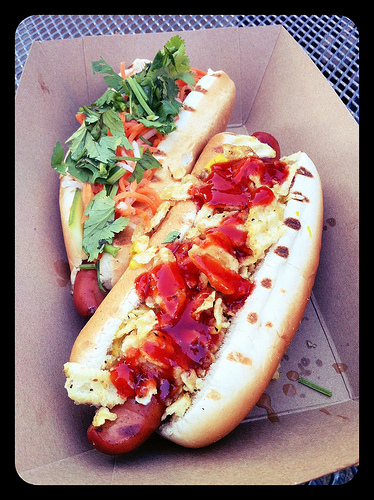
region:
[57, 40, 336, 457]
gourmet hotdogs in a tray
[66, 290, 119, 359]
white bun of a hotdog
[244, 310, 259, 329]
brown spot on bun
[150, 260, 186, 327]
sauce on a hotdog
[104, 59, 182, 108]
green cilantro on a hotdog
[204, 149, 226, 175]
mustard on a hotdog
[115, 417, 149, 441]
grill mark on a hotdog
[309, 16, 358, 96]
metal table under hotdogs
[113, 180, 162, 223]
tomatoes on a hotdog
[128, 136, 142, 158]
onion on a hotdog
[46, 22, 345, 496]
Two hot dogs in a box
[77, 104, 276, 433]
Hot dogs on buns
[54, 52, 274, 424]
The buns are white bread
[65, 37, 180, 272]
Cilantro on the hot dog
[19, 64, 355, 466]
The box is brown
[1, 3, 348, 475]
Photo taken during the day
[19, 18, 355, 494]
No people pictured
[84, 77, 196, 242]
Shredded carrots on the hot dog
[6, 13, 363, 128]
The table is metal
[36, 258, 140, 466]
The hot dogs are brown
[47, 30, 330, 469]
gourmet dotdogs in a tray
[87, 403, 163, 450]
hotdog on a bun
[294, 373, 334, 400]
herb in a tray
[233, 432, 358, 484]
cardboard tray holding hotdogs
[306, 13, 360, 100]
metal table holding hotdogs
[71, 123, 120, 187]
green cilantro on a hotdog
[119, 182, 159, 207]
tomato on a hotdog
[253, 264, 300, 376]
white hotdog bun on a tray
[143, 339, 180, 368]
ketchup on a hotdog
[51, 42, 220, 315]
a hot dog with green lettuce on top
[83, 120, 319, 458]
a loaded hot dog in a bun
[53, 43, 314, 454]
two loaded hot dogs in hot dog buns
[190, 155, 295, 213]
a dollop of ketchup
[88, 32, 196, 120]
a few leafy greens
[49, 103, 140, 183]
a few sprigs of baby spinach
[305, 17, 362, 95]
wire table top mesh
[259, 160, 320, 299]
grill marks on a hot dog bun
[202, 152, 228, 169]
a dash of mustard on ketchup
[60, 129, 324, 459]
a Chicago hot dog loaded with everything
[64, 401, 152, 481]
tip of the hot dog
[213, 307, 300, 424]
bread of the hot dog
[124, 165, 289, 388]
ketchup in the hot dog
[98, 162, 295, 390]
toppings on the hot dog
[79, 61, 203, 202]
toppings on the other hot dog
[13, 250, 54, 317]
box next to hot dogs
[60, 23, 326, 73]
back of the box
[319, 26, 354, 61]
table next to the box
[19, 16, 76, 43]
holes in the table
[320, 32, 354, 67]
top of the table